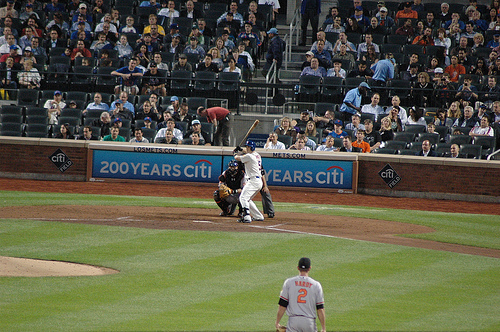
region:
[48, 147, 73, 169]
citi logo on the wall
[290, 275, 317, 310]
number two of man's shirt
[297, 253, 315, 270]
black hat on baseball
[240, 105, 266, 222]
baseball batter up to bat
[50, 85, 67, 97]
blue cap on man's head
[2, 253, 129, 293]
pitchers mound filled with dirt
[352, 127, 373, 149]
man with orange shirt on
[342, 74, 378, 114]
man with blue shirt on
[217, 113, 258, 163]
wooden bat held by batter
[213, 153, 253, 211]
catcher sitting behind batter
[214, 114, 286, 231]
A man holding a baseball bat.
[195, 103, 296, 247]
An athlete playing a game of baseball.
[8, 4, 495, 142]
Spectators sitting in stands watching a ball game.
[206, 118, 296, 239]
A man wearing a blue baseball helmet.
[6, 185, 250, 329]
A green baseball playing field.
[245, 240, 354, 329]
An athlete in a gray and orange uniform.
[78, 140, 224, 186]
Blue sign behind a batter.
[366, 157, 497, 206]
A brick wall separating players and spectators.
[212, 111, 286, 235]
A male wearing a white baseball uniform.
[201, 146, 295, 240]
A catcher kneeling behind a batter.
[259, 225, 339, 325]
player in gray on field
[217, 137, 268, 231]
batter in white uniform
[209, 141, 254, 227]
catcher squatting behind batter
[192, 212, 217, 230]
white home plate by batter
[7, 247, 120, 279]
clay pitchers mound on left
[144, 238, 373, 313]
neatly trimmed green field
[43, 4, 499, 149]
crowd watching baseball game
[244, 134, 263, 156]
blue helmet on batter's head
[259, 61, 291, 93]
metal rails along stairs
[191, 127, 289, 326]
These are baseball players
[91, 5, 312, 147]
These are fans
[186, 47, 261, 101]
This is the stands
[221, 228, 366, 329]
This is a baseball player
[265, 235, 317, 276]
This is a baseball cap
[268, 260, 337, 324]
The shirt is grey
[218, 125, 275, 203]
The shirt is white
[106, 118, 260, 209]
This is a sponsor banner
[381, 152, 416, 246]
This says "citi"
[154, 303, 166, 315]
The grass is freshly mowed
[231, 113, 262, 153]
wooden base ball bat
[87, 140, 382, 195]
long blue advertising sign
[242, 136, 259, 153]
hard blue batters helmet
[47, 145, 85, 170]
black triangle advertising sign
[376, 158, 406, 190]
black triangle advertising sign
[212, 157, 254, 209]
batcher at homeplate in baseball game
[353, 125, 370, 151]
boy in ornage short sleeve shirt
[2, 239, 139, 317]
edge on putchers mound on ball field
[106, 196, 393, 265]
white lines painted on ball field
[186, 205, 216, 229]
white home plate in ball game